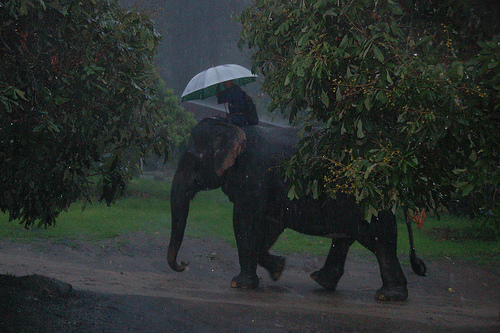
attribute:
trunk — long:
[167, 187, 192, 274]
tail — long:
[394, 194, 446, 288]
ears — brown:
[207, 122, 247, 178]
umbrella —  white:
[179, 60, 260, 100]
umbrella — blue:
[162, 48, 256, 101]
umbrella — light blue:
[167, 53, 267, 131]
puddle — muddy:
[0, 252, 207, 299]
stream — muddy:
[136, 281, 423, 315]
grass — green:
[1, 172, 498, 267]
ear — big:
[203, 107, 256, 177]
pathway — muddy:
[3, 229, 498, 330]